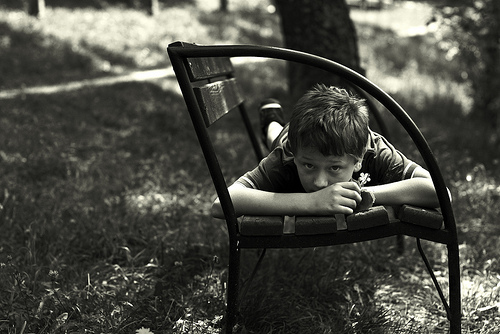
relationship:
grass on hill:
[67, 138, 190, 264] [8, 11, 492, 324]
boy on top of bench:
[261, 90, 419, 217] [171, 36, 471, 327]